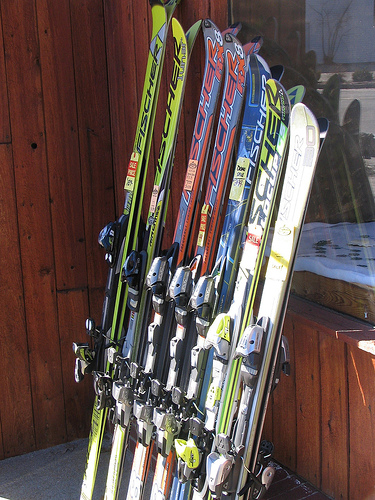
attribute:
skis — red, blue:
[74, 0, 180, 498]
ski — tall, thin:
[207, 101, 321, 497]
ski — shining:
[214, 99, 331, 499]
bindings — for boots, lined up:
[63, 237, 277, 475]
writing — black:
[142, 63, 152, 156]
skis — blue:
[157, 50, 254, 341]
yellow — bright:
[163, 22, 194, 47]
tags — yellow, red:
[120, 148, 256, 255]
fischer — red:
[200, 49, 237, 217]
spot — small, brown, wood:
[306, 370, 314, 383]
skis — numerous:
[112, 42, 319, 360]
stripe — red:
[246, 230, 262, 246]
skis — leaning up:
[52, 3, 363, 499]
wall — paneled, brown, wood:
[12, 66, 110, 366]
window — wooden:
[292, 0, 367, 99]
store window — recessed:
[219, 1, 372, 129]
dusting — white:
[2, 429, 180, 498]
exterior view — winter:
[294, 5, 373, 285]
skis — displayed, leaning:
[73, 5, 327, 497]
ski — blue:
[170, 54, 271, 498]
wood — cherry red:
[255, 291, 373, 498]